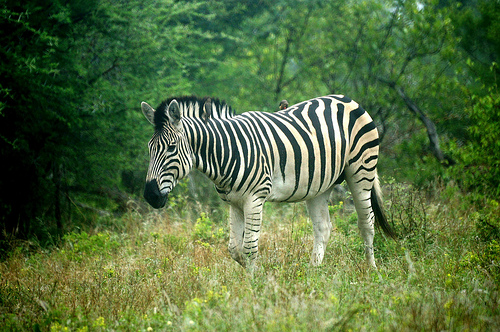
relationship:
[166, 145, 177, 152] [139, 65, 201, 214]
eye are on head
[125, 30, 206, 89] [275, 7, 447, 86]
leaves on tree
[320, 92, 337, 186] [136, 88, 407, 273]
stripe on zebra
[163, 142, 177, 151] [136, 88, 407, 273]
eye of a zebra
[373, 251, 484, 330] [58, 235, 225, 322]
flowers on grass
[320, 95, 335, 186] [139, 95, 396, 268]
stripe on zebra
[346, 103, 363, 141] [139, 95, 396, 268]
stripe on zebra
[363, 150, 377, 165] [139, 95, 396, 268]
stripe on zebra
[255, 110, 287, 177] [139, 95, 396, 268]
stripe on zebra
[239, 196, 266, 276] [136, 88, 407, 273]
leg on zebra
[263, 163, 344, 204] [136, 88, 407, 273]
belly on zebra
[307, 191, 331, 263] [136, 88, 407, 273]
leg on zebra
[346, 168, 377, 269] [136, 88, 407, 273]
leg on zebra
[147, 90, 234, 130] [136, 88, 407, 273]
mane on zebra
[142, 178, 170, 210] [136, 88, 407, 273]
nose on zebra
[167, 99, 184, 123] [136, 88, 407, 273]
ear on zebra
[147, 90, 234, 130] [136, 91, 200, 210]
mane on head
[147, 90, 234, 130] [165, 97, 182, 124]
mane near ear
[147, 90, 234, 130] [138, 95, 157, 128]
mane near ear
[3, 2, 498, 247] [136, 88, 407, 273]
trees behind zebra